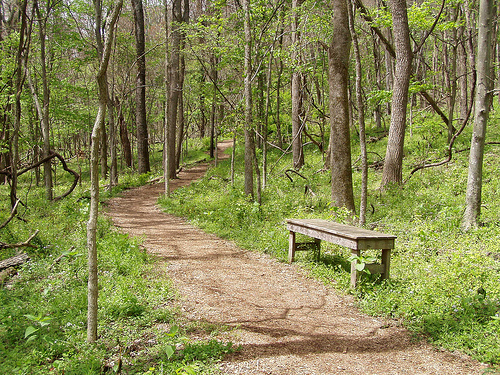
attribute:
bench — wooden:
[285, 232, 320, 266]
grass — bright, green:
[438, 309, 493, 359]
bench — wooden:
[284, 215, 396, 295]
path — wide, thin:
[101, 139, 493, 373]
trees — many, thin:
[263, 10, 463, 230]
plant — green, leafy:
[19, 309, 61, 360]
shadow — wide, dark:
[212, 317, 427, 361]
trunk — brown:
[376, 1, 413, 193]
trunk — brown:
[322, 0, 354, 220]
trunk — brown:
[459, 0, 496, 237]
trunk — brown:
[156, 0, 201, 208]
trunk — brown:
[286, 0, 307, 181]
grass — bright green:
[417, 255, 489, 332]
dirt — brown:
[200, 273, 251, 303]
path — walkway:
[117, 195, 445, 366]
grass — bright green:
[109, 285, 140, 327]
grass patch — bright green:
[197, 169, 306, 248]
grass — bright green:
[20, 300, 65, 351]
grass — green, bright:
[24, 206, 105, 281]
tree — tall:
[155, 5, 184, 209]